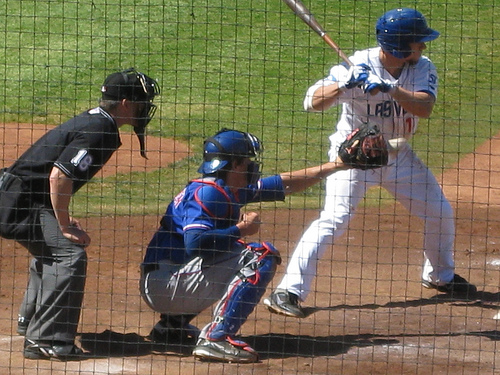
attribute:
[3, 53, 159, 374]
umpire — crouching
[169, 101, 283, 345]
catcher — kneeling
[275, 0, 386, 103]
bat — brown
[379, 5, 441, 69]
helmet — blue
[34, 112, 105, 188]
t shirt — black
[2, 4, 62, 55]
grass — green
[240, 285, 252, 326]
shin pads — blue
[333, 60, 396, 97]
two gloves — white, blue